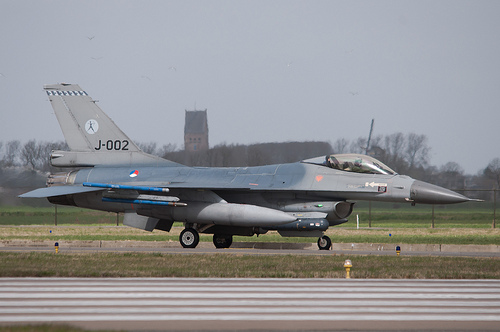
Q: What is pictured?
A: A jet.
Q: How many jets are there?
A: 1.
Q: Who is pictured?
A: No one.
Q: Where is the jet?
A: On the ground.